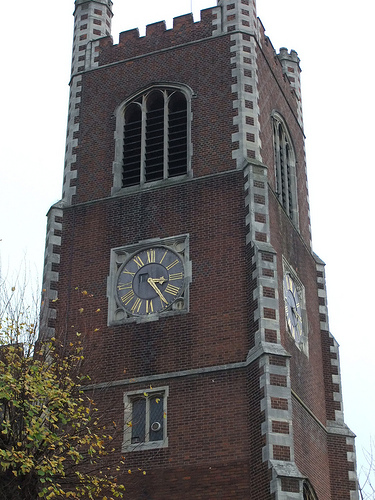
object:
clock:
[107, 232, 192, 327]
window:
[121, 386, 170, 454]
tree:
[0, 286, 125, 500]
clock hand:
[147, 276, 168, 285]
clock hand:
[147, 277, 168, 304]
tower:
[55, 1, 319, 211]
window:
[110, 80, 194, 197]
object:
[151, 422, 161, 432]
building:
[33, 0, 359, 498]